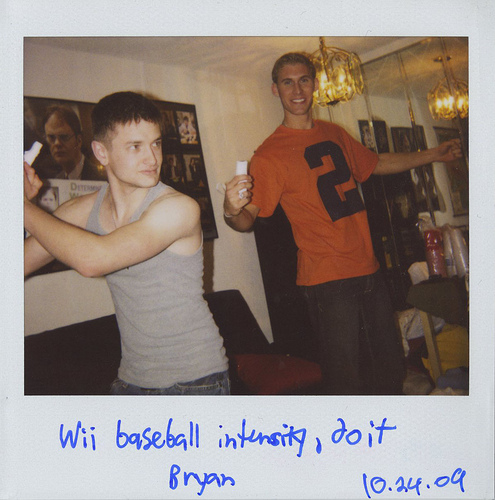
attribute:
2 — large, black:
[299, 137, 373, 219]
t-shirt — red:
[264, 112, 392, 294]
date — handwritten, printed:
[370, 457, 475, 497]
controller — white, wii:
[230, 156, 255, 211]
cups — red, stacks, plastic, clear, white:
[417, 225, 449, 273]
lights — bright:
[323, 49, 368, 108]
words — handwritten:
[134, 430, 220, 442]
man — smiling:
[77, 84, 226, 389]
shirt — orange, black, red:
[290, 124, 366, 274]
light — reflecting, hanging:
[310, 78, 359, 110]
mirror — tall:
[358, 97, 429, 150]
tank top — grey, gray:
[99, 193, 228, 384]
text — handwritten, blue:
[54, 430, 290, 486]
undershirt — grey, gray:
[118, 269, 247, 385]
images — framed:
[165, 99, 234, 192]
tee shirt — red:
[268, 212, 384, 254]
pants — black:
[297, 282, 400, 373]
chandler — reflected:
[410, 48, 460, 124]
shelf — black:
[408, 275, 474, 326]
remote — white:
[229, 151, 267, 209]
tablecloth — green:
[429, 301, 458, 318]